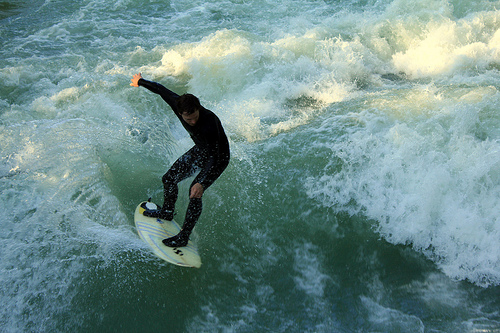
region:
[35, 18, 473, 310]
the ocean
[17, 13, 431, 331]
surfing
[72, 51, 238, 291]
a man surfing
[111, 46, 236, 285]
the man is surfing in the ocean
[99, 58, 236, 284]
the surfer is wearing a wetsuit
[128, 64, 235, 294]
the surfer is wearing black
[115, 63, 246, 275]
the man is standing on the surfboard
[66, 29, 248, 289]
the surfer is riding a wave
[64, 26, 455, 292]
the water is very choppy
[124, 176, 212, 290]
the surfboard is yellow with a blue pattern on it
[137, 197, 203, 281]
A large surf board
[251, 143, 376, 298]
A large ocean wave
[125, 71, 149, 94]
The hand of a man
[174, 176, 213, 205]
The hand of a man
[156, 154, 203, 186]
A mans right thigh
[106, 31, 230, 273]
A surfer on a board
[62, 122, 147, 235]
A wake coming from board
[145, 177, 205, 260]
Both of surfers legs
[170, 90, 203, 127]
A surfers head with hair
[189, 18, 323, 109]
A wave crashing in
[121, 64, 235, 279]
man on surfboard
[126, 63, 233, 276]
man in black wet suit on surfboard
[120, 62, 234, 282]
man on surfboard riding the waves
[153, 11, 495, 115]
sunshine hitting the water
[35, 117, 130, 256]
rooster tail made by surfboard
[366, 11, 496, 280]
foam from crashing waves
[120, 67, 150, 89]
man's hand in the sun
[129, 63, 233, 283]
man's body in the shade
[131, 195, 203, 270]
white surfboard on the water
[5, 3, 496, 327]
man on surfboard surrounded by waves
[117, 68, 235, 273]
man in black surfing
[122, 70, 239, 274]
man is wearing a black wetsuit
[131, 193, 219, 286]
feet are firmly planted on surfboard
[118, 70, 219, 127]
man has his right arm sticking out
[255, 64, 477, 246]
seas are rough looking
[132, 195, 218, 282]
surf board has blue stripes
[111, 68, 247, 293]
the man is standing up on the surfboard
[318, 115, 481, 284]
white peaks from breaking waves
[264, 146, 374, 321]
the water is grey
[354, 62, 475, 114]
sunlight is bright on the waves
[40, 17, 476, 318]
surfer riding the waves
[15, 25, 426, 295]
surfer riding the beautiful waves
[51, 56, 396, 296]
surfer riding the awesome waves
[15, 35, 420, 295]
surfer riding the ocean waves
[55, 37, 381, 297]
surfer riding the great waves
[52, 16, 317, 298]
surfer riding some waves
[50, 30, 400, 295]
surfer riding the big waves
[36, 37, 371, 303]
surfer riding the strong waves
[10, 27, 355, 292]
surfer riding the attractive waves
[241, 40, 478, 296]
some really beautiful ocean waves